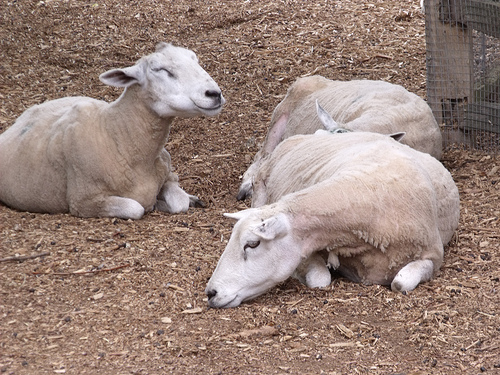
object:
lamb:
[0, 42, 226, 220]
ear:
[99, 68, 140, 88]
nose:
[205, 90, 218, 97]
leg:
[103, 196, 145, 220]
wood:
[423, 0, 470, 146]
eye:
[248, 241, 260, 248]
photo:
[3, 1, 500, 375]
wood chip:
[125, 243, 130, 248]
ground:
[0, 0, 499, 375]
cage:
[423, 0, 500, 150]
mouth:
[190, 98, 224, 116]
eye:
[153, 68, 173, 78]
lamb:
[204, 134, 460, 308]